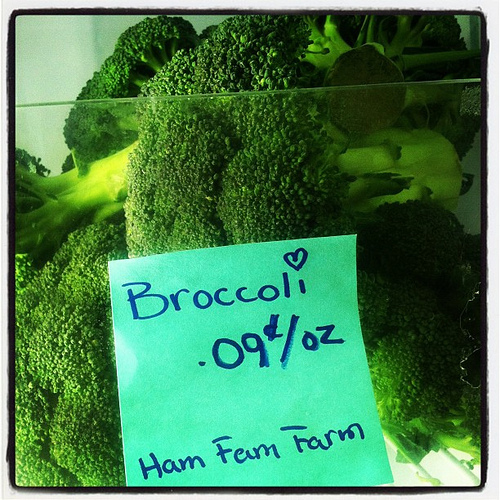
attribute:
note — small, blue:
[106, 231, 396, 488]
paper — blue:
[120, 273, 334, 455]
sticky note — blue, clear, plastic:
[99, 225, 397, 492]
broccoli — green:
[122, 16, 479, 447]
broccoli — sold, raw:
[18, 17, 489, 487]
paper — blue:
[106, 228, 386, 496]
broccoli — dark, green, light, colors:
[122, 15, 467, 218]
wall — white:
[16, 13, 145, 177]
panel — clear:
[49, 97, 447, 285]